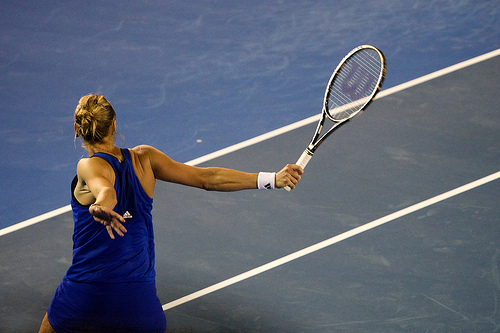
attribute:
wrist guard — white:
[252, 156, 280, 229]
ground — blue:
[2, 1, 498, 331]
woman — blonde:
[28, 83, 311, 332]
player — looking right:
[30, 84, 308, 329]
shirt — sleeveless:
[52, 146, 164, 296]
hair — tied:
[70, 103, 113, 137]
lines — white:
[166, 39, 496, 329]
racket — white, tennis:
[279, 39, 389, 197]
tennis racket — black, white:
[275, 37, 395, 197]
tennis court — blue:
[126, 8, 309, 108]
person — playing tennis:
[32, 79, 313, 331]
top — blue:
[55, 144, 164, 302]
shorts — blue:
[37, 277, 175, 331]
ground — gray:
[352, 235, 490, 325]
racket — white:
[272, 42, 401, 190]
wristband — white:
[255, 167, 278, 195]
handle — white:
[275, 148, 316, 196]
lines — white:
[6, 44, 484, 294]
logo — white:
[117, 208, 137, 226]